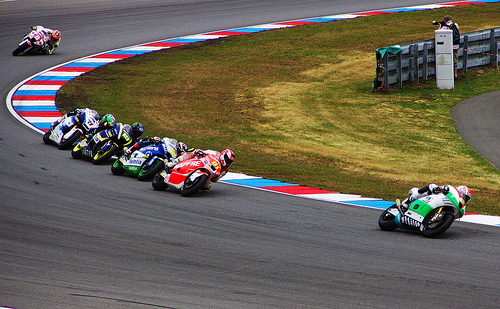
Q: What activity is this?
A: Motorcycle racing.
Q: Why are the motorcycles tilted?
A: They are rounding a curve.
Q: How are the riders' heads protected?
A: Helmets.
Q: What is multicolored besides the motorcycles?
A: The ring around the inside of the track.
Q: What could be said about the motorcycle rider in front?
A: He's winning.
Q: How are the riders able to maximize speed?
A: By leaning over.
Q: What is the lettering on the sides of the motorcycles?
A: Advertisements and sponsors.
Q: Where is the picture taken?
A: A race.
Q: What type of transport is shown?
A: Motorcycles.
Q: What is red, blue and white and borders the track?
A: Stripes.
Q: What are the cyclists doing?
A: Competing.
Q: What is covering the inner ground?
A: Grass.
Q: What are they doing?
A: Racing.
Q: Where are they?
A: On a track.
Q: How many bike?
A: Six.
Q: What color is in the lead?
A: The green one.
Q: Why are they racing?
A: To win trophy.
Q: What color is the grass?
A: Green.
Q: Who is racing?
A: Guys.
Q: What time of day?
A: Afternoon.